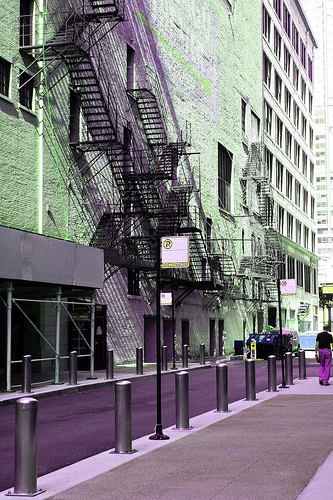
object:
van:
[269, 328, 300, 360]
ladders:
[10, 0, 226, 297]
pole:
[147, 234, 169, 442]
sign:
[158, 290, 174, 305]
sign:
[278, 278, 297, 296]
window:
[283, 84, 288, 116]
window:
[302, 151, 307, 178]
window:
[294, 27, 298, 53]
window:
[261, 1, 264, 38]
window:
[306, 55, 311, 79]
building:
[0, 0, 317, 390]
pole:
[14, 394, 39, 496]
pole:
[112, 380, 133, 458]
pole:
[174, 370, 191, 432]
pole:
[215, 362, 231, 413]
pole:
[243, 355, 255, 399]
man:
[312, 321, 332, 386]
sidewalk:
[0, 361, 211, 407]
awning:
[0, 225, 103, 290]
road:
[0, 358, 314, 486]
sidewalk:
[0, 372, 332, 499]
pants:
[317, 348, 330, 387]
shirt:
[315, 331, 331, 348]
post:
[14, 302, 63, 359]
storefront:
[263, 225, 321, 358]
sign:
[159, 235, 190, 272]